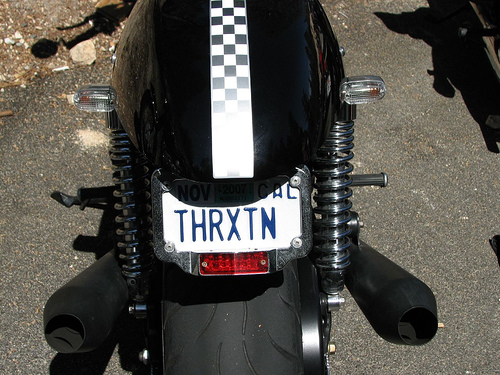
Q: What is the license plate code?
A: THRXTN.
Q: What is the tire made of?
A: Rubber.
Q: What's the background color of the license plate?
A: White.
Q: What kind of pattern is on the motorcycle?
A: Checkers.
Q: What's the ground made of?
A: Asphalt.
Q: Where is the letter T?
A: On the license plate.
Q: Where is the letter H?
A: On the license plate.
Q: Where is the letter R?
A: On the license plate.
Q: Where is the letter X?
A: On the license plates.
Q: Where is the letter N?
A: On the license plate.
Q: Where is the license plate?
A: On the bike.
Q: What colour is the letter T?
A: On the sign.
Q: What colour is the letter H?
A: On the license plate.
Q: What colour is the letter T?
A: On the license plate.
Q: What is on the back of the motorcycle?
A: A license plate.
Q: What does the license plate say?
A: THRXTN.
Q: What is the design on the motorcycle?
A: A black and white checkered stripe.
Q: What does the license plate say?
A: THRXTN.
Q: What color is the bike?
A: Black.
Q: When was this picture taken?
A: Daytime.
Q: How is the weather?
A: Sunny.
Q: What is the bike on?
A: Asphalt.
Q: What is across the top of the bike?
A: Checkered pattern.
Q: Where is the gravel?
A: Along side the road.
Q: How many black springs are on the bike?
A: Two.